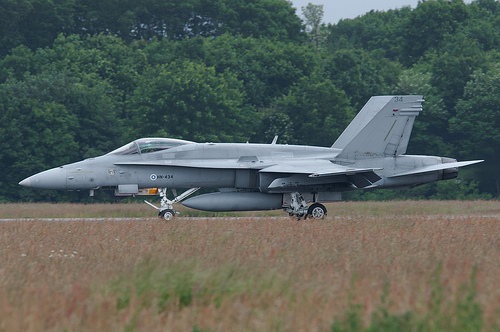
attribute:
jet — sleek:
[18, 95, 484, 221]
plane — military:
[17, 95, 484, 220]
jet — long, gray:
[4, 91, 489, 247]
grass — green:
[205, 249, 292, 305]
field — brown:
[198, 234, 399, 284]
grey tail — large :
[330, 93, 426, 162]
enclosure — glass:
[106, 133, 190, 155]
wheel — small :
[152, 202, 181, 224]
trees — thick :
[88, 29, 321, 104]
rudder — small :
[271, 132, 283, 142]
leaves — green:
[406, 5, 498, 161]